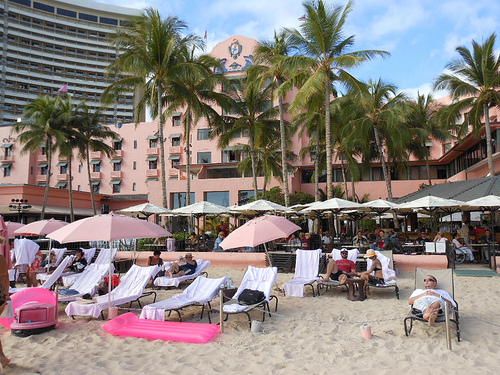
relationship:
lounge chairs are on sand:
[1, 247, 464, 349] [3, 267, 500, 372]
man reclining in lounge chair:
[409, 274, 459, 327] [401, 262, 461, 356]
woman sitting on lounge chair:
[358, 247, 388, 296] [357, 244, 401, 302]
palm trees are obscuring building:
[9, 0, 498, 219] [3, 33, 497, 204]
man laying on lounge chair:
[409, 274, 459, 327] [401, 262, 461, 356]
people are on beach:
[1, 214, 461, 368] [1, 3, 498, 375]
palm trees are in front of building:
[9, 0, 498, 219] [3, 33, 497, 204]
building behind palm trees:
[3, 33, 497, 204] [9, 0, 498, 219]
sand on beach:
[3, 267, 500, 372] [1, 3, 498, 375]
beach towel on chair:
[283, 244, 322, 299] [272, 240, 323, 298]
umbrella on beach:
[216, 214, 304, 294] [1, 3, 498, 375]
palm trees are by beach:
[9, 0, 498, 219] [1, 3, 498, 375]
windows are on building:
[38, 135, 125, 193] [3, 33, 497, 204]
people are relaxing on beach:
[1, 214, 461, 368] [1, 3, 498, 375]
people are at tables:
[209, 219, 499, 256] [193, 230, 498, 248]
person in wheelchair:
[447, 232, 477, 265] [452, 244, 467, 265]